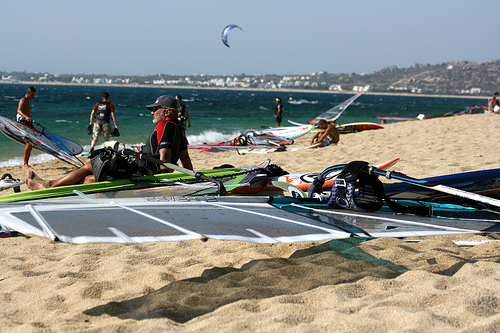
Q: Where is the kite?
A: In the sky.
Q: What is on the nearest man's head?
A: A baseball cap.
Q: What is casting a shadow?
A: A white surfboard.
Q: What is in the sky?
A: A kite.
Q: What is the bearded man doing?
A: Lounging on the beach.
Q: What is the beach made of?
A: Sand.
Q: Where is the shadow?
A: Under the surfboard.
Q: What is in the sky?
A: Colorful flying devices.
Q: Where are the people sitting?
A: On a sandy beach.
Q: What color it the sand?
A: Brown.